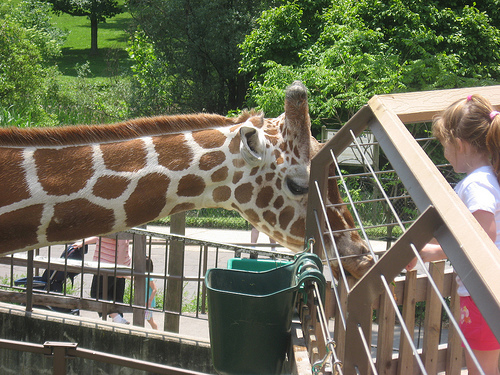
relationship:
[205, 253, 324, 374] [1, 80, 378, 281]
bins for giraffe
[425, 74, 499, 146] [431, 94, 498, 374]
hair of girl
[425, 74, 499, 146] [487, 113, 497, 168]
hair in ponytail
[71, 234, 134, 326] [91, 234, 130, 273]
girl wearing shirt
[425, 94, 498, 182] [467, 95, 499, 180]
hair in ponytail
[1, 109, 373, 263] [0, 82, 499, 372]
giraffe in zoo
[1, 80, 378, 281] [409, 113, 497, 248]
giraffe being fed by girl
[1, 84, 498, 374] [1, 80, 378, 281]
pen of giraffe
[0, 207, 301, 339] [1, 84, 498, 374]
fence around pen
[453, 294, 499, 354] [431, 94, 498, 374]
shorts of girl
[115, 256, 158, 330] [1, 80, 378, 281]
child behind giraffe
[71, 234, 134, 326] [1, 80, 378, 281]
girl behind giraffe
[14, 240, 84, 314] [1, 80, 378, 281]
stroller behind giraffe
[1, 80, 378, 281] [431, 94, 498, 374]
giraffe eating by girl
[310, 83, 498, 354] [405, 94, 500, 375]
railing by child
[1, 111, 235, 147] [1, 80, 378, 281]
hair on giraffe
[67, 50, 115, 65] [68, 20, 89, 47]
shadow on grass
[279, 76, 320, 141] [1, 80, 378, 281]
horns on giraffe